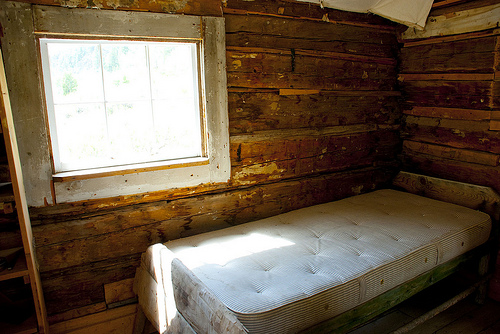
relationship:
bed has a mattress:
[134, 169, 499, 333] [161, 188, 493, 334]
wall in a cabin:
[2, 1, 404, 329] [2, 1, 499, 332]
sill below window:
[50, 156, 210, 184] [37, 35, 211, 173]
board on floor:
[106, 274, 141, 307] [5, 289, 499, 334]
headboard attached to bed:
[392, 168, 499, 213] [134, 169, 499, 333]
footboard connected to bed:
[165, 250, 250, 334] [134, 169, 499, 333]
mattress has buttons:
[161, 188, 493, 334] [241, 213, 415, 289]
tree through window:
[51, 44, 135, 111] [2, 4, 238, 210]